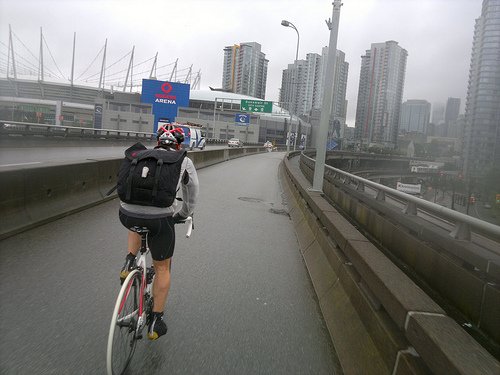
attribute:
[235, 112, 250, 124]
sign — blue, white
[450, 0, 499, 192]
skyscraper — tall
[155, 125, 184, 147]
bicycle helmet — black, red, white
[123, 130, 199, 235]
bag — black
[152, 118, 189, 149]
helmet — black, red, white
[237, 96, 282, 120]
street sign — green, white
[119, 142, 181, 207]
backpack — black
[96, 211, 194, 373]
bike — white, red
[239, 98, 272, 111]
street sign — green, white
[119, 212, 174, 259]
shorts — black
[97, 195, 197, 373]
bike — white, red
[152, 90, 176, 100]
lettering — red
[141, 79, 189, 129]
sign — blue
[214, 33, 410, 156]
buildings — tall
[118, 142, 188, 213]
shirt — gray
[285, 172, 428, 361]
concrete barrier — flat-topped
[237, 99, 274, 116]
road sign — green